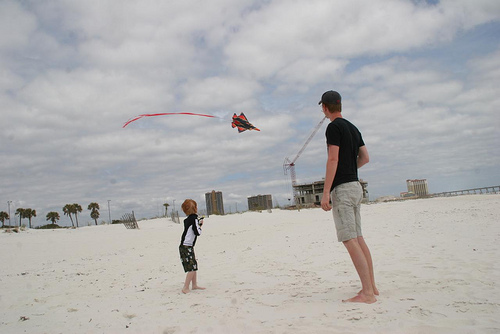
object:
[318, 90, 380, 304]
man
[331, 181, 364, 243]
shorts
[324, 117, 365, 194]
shirt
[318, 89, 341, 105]
hat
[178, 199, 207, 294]
boy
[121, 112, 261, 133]
kite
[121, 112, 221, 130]
tail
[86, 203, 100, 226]
palm trees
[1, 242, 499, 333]
sand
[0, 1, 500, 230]
sky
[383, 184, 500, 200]
pier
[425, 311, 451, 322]
footprints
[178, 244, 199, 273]
shorts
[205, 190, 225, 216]
buildings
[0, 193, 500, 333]
beach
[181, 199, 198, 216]
hair